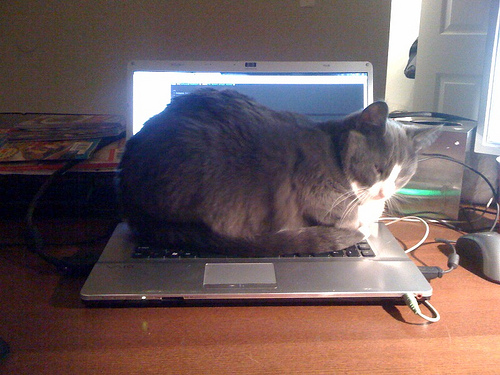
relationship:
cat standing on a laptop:
[115, 86, 445, 258] [65, 52, 430, 309]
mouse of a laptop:
[456, 231, 500, 285] [72, 50, 418, 330]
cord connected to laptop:
[401, 293, 440, 323] [65, 52, 430, 309]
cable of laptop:
[23, 145, 106, 271] [65, 52, 430, 309]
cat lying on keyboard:
[115, 86, 445, 258] [120, 217, 375, 264]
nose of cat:
[370, 183, 390, 203] [115, 86, 445, 258]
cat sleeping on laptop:
[115, 86, 445, 258] [65, 52, 430, 309]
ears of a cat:
[347, 91, 454, 151] [115, 86, 445, 258]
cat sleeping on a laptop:
[115, 86, 445, 258] [65, 52, 430, 309]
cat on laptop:
[115, 86, 445, 258] [103, 40, 399, 360]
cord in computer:
[401, 293, 440, 323] [97, 49, 392, 313]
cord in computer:
[31, 230, 140, 306] [130, 50, 450, 314]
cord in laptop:
[398, 294, 448, 326] [119, 35, 420, 341]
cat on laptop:
[158, 110, 425, 253] [119, 35, 420, 341]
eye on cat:
[369, 162, 384, 176] [70, 93, 370, 258]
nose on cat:
[376, 188, 388, 199] [158, 110, 425, 253]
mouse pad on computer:
[203, 262, 279, 285] [79, 58, 434, 308]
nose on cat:
[376, 188, 388, 199] [124, 85, 410, 185]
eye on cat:
[369, 162, 384, 176] [124, 107, 384, 257]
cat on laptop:
[158, 110, 425, 253] [124, 62, 431, 321]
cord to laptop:
[379, 152, 500, 283] [115, 227, 416, 315]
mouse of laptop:
[456, 218, 477, 290] [112, 252, 429, 300]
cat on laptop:
[115, 86, 445, 258] [88, 232, 400, 295]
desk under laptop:
[188, 332, 280, 368] [125, 246, 415, 290]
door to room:
[420, 30, 476, 95] [39, 21, 478, 361]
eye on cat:
[369, 162, 384, 176] [115, 86, 445, 258]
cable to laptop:
[63, 132, 108, 187] [138, 245, 398, 317]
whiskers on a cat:
[345, 192, 363, 224] [127, 84, 413, 247]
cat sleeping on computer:
[115, 86, 445, 258] [79, 58, 434, 308]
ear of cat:
[359, 101, 388, 137] [80, 80, 423, 265]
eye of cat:
[369, 162, 384, 176] [101, 71, 425, 268]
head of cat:
[325, 90, 453, 213] [105, 71, 458, 279]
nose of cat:
[376, 188, 388, 199] [115, 86, 445, 258]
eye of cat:
[369, 162, 384, 176] [117, 90, 458, 280]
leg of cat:
[118, 112, 365, 257] [115, 86, 445, 258]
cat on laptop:
[115, 86, 445, 258] [65, 52, 430, 309]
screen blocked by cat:
[131, 70, 367, 137] [115, 86, 445, 258]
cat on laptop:
[115, 86, 445, 258] [81, 57, 431, 296]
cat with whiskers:
[115, 86, 445, 258] [332, 186, 367, 221]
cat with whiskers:
[115, 86, 445, 258] [329, 186, 392, 240]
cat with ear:
[115, 86, 445, 258] [359, 102, 390, 135]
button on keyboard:
[166, 249, 181, 258] [135, 216, 375, 257]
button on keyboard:
[355, 248, 374, 257] [138, 226, 374, 259]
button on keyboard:
[332, 246, 344, 257] [130, 232, 375, 257]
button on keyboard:
[340, 243, 357, 258] [75, 200, 430, 305]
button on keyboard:
[135, 246, 150, 261] [135, 234, 371, 254]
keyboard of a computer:
[122, 240, 381, 295] [79, 51, 409, 312]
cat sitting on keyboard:
[115, 86, 445, 258] [122, 240, 381, 295]